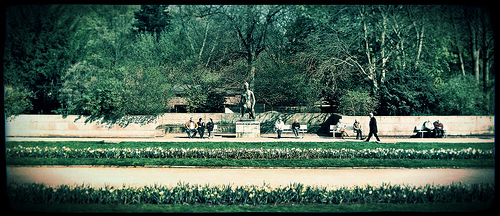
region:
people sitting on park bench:
[184, 115, 224, 137]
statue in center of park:
[230, 70, 265, 137]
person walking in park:
[364, 105, 386, 143]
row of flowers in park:
[12, 141, 494, 168]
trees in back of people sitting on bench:
[6, 2, 208, 113]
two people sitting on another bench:
[270, 112, 315, 139]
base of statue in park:
[237, 118, 263, 139]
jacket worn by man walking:
[362, 115, 380, 134]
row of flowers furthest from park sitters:
[22, 179, 467, 214]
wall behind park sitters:
[452, 118, 497, 133]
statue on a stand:
[203, 81, 273, 181]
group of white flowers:
[317, 139, 465, 162]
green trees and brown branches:
[249, 12, 434, 118]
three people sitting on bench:
[147, 105, 212, 172]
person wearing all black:
[357, 106, 384, 151]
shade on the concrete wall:
[242, 100, 334, 130]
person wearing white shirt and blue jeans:
[265, 109, 292, 146]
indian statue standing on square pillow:
[220, 71, 290, 123]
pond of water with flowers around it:
[0, 143, 452, 210]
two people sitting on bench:
[394, 110, 456, 151]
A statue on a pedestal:
[230, 77, 266, 143]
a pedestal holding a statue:
[232, 118, 262, 142]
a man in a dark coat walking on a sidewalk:
[364, 109, 382, 145]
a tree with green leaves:
[65, 52, 172, 110]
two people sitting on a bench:
[414, 112, 446, 138]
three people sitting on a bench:
[180, 115, 223, 142]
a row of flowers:
[49, 141, 455, 165]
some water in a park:
[104, 162, 390, 192]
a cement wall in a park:
[26, 105, 142, 141]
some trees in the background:
[354, 19, 426, 67]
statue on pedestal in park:
[233, 80, 260, 134]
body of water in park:
[1, 163, 498, 189]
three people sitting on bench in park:
[173, 118, 220, 136]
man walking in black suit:
[363, 113, 378, 140]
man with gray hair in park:
[363, 108, 383, 143]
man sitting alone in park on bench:
[273, 118, 315, 141]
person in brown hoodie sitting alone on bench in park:
[329, 118, 364, 143]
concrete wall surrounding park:
[6, 112, 493, 139]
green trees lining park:
[8, 0, 496, 126]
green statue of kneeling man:
[238, 80, 255, 119]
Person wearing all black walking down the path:
[362, 109, 379, 141]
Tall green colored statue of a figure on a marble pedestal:
[237, 76, 256, 129]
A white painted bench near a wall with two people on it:
[327, 116, 363, 141]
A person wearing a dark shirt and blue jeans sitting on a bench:
[289, 117, 304, 139]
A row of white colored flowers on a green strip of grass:
[77, 141, 433, 163]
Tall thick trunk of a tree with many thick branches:
[223, 4, 261, 74]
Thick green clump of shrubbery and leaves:
[48, 47, 178, 107]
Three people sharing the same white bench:
[183, 113, 216, 141]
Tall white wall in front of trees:
[24, 109, 177, 131]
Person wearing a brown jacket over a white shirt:
[184, 117, 199, 135]